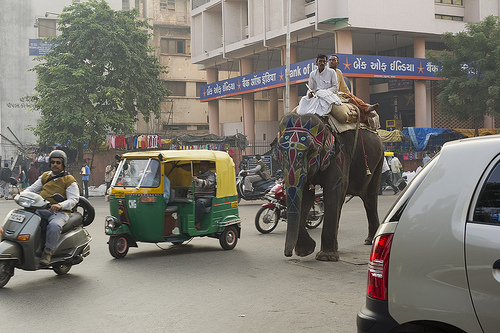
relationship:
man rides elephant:
[329, 54, 380, 112] [280, 55, 385, 263]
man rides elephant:
[296, 53, 343, 116] [280, 55, 385, 263]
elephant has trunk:
[275, 107, 383, 259] [277, 155, 301, 257]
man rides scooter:
[242, 155, 267, 192] [236, 172, 274, 199]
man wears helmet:
[13, 150, 80, 265] [46, 150, 67, 168]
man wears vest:
[17, 149, 89, 259] [38, 173, 74, 200]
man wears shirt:
[17, 149, 89, 259] [18, 171, 80, 208]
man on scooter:
[17, 149, 89, 259] [0, 188, 101, 290]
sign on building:
[199, 54, 478, 102] [189, 0, 498, 158]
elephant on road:
[270, 113, 384, 262] [0, 242, 364, 333]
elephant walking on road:
[270, 113, 384, 262] [69, 242, 364, 331]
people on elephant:
[303, 49, 383, 116] [265, 100, 390, 265]